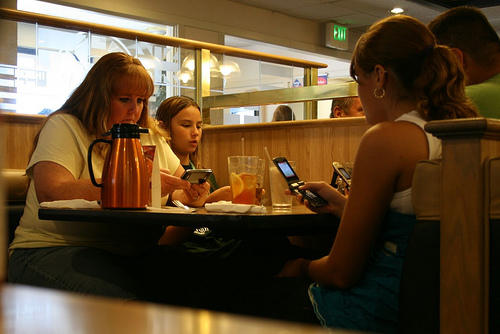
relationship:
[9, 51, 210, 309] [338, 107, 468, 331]
mom sitting in restaurant booth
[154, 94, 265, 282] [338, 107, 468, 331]
person sitting in restaurant booth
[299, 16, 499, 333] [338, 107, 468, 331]
person sitting in restaurant booth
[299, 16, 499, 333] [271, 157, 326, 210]
person holding cell phone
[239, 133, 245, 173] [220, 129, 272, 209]
straw in glass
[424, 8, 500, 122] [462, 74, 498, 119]
male wearing shirt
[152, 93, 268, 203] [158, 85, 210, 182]
girl has hair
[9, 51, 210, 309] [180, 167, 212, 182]
mom focused on cell phone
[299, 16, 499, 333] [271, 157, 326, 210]
person focused on cell phone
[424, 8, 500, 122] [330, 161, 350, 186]
male focused on cell phone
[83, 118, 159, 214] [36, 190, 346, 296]
pot on table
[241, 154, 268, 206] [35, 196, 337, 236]
cup on table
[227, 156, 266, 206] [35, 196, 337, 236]
cup on table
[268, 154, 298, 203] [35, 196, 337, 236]
cup on table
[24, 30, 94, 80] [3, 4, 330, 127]
glass on divider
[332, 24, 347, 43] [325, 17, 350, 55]
lettering on sign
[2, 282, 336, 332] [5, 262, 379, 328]
surface on table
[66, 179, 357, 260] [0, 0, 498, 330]
table in restaurant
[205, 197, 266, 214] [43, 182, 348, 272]
napkin on table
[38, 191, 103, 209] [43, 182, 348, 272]
napkin on table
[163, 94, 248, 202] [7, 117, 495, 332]
person in booth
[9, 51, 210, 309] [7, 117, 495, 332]
mom in booth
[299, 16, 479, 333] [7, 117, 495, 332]
person in booth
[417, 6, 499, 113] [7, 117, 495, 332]
person in booth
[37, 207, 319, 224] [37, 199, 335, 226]
edge of table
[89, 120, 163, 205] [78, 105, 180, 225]
carafe of coffee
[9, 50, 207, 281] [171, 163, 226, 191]
mom on cell phone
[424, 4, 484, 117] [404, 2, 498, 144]
male on phone